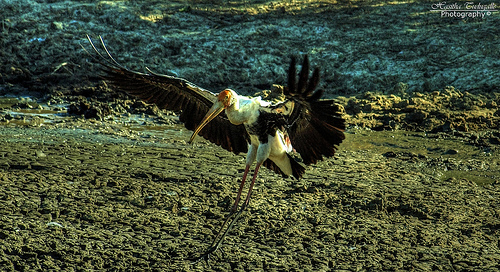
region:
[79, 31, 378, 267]
Large bird with wings spread out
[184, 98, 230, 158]
Long white beak on bird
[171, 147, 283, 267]
Two long orange legs on bird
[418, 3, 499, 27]
White lettering in corner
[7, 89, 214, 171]
Small piles of water on the ground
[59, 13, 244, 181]
Bird has black wings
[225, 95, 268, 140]
White neck on bird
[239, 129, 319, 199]
Bird has black and white tail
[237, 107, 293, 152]
Black part of bird under chest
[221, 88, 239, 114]
Bird has orange head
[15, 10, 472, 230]
this is a nature setting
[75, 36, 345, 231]
this is a big bird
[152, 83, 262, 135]
the bird has a long beak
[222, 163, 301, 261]
the bird has very long legs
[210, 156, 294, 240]
the bird's legs are very skinny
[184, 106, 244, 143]
the bird has a yellow beak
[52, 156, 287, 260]
the ground here is sand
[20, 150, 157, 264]
the sand is medium light brown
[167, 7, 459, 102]
the background is turqoise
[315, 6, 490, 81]
part of the water is dark turqoise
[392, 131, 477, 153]
Small puddle of water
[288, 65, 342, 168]
Dark wing stretched out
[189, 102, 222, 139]
Long beak on bird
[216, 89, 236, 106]
Reddish orange head on bird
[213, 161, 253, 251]
Long skinny bird legs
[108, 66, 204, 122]
Long bird wing with dark feathers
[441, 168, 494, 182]
Small puddle of muddy water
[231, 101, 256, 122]
White patch on bird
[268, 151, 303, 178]
White tail on bird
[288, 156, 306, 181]
Dark tail feathers on bird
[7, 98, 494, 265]
rough brown rocky surface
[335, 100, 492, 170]
water in rocky depression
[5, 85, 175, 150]
shallow water over rock edge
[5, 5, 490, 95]
swirling and churning water below slope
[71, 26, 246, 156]
wide wing span of dark feathers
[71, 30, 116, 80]
individual wing feathers curling up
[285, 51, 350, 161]
black feathers in a fan shape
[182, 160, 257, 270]
long twig-like legs gently angled forward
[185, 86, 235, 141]
closed long and pointy beak at end of orange head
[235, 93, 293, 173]
black band around middle of white body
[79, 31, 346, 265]
A large mostly black and white bird.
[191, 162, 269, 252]
Extremely long brown and orange colored bird legs.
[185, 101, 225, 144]
Long white and light orange beak of a bird.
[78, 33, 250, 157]
A birds right side black, white and brown wing.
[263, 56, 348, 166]
A left side wing of a bird.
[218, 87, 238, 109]
Orange, yellow and white head of a bird.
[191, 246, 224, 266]
The grey feet of a bird.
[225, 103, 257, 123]
A white crooked neck of a bird.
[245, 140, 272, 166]
The top white legs of a bird.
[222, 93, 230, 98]
A black eye of a bird.